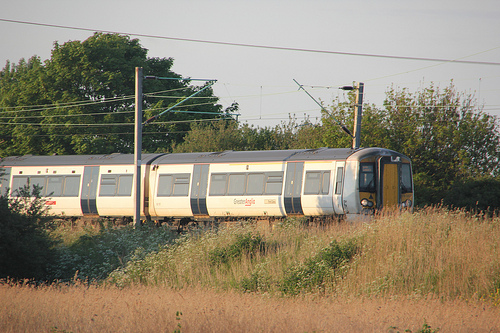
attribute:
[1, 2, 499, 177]
sky — grey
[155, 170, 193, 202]
window — two pane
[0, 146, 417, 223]
train — black , grey, Beige, blue, white, Yellow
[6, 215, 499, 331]
grassy field — dry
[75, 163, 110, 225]
door — rear passenger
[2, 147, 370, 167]
top — grey 